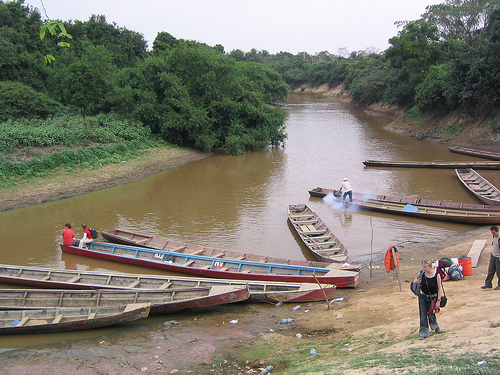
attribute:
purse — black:
[434, 280, 450, 308]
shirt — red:
[64, 220, 75, 254]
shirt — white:
[336, 180, 352, 197]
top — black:
[418, 273, 449, 301]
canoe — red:
[73, 256, 271, 277]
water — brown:
[228, 101, 411, 229]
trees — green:
[189, 72, 287, 153]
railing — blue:
[98, 240, 328, 281]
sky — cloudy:
[191, 22, 386, 51]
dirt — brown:
[64, 164, 166, 190]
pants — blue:
[418, 296, 444, 338]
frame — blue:
[91, 244, 138, 259]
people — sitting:
[63, 215, 94, 255]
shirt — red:
[80, 226, 97, 244]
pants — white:
[83, 235, 94, 249]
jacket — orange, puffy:
[386, 250, 406, 275]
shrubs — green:
[10, 136, 152, 170]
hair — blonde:
[426, 258, 438, 269]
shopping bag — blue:
[401, 205, 425, 212]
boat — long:
[319, 181, 474, 213]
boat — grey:
[455, 169, 499, 205]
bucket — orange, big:
[464, 254, 473, 280]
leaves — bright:
[46, 12, 71, 63]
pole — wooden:
[395, 259, 400, 298]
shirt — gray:
[490, 231, 499, 256]